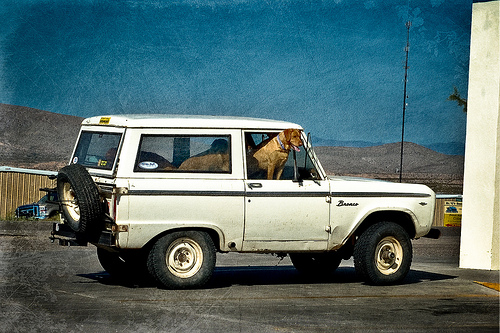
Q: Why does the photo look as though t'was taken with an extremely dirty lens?
A: Photo effects.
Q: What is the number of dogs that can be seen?
A: 2.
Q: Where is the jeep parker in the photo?
A: Parking lot.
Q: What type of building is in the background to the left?
A: Pole barn.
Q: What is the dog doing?
A: Hanging out the window.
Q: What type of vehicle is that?
A: Old school bronco.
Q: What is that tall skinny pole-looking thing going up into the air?
A: Antenna.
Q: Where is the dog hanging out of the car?
A: Passenger window.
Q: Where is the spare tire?
A: Back of white car.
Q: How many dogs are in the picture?
A: Two.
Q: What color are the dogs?
A: Tan.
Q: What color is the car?
A: White.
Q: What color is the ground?
A: Black.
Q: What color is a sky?
A: Blue.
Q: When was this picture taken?
A: During the day.